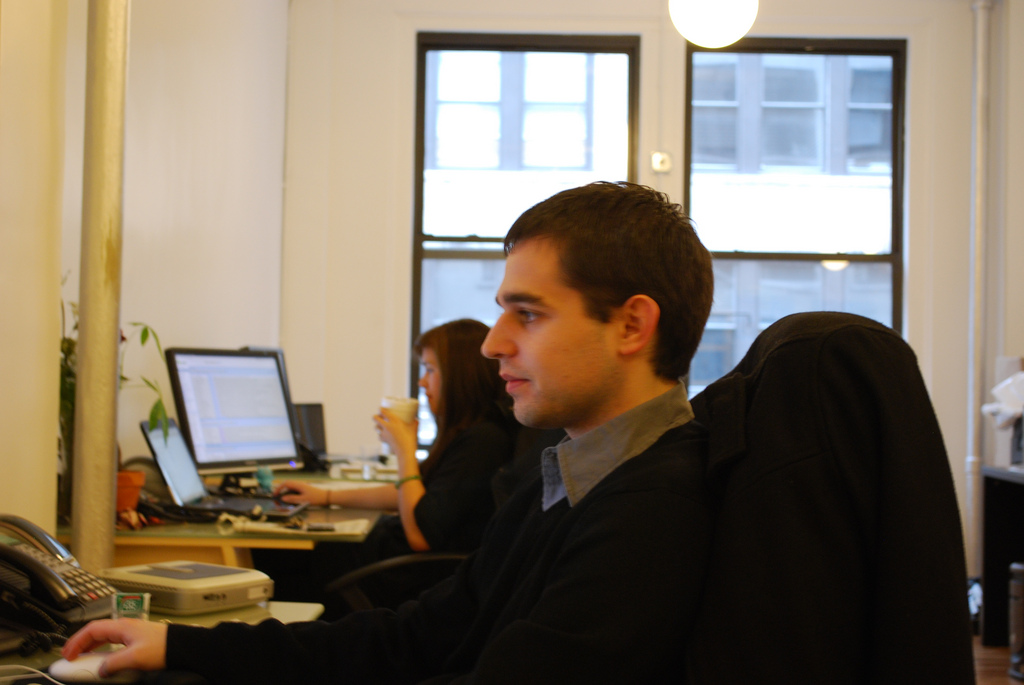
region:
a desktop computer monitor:
[168, 344, 306, 477]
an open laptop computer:
[136, 413, 305, 527]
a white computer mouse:
[52, 654, 103, 678]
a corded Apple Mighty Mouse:
[49, 651, 116, 678]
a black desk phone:
[4, 508, 122, 630]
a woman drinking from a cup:
[276, 316, 540, 550]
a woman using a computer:
[138, 318, 543, 550]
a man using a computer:
[49, 181, 752, 681]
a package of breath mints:
[111, 587, 150, 620]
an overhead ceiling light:
[667, 0, 760, 51]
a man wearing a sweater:
[405, 222, 799, 676]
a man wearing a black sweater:
[388, 186, 762, 662]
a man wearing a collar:
[449, 173, 808, 607]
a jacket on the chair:
[688, 263, 996, 671]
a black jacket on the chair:
[679, 303, 1022, 636]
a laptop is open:
[130, 414, 307, 573]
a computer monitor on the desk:
[179, 335, 322, 484]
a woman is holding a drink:
[378, 320, 522, 567]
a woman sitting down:
[364, 319, 514, 618]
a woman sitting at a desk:
[340, 326, 517, 527]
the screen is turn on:
[157, 333, 314, 485]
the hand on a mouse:
[28, 603, 207, 681]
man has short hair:
[436, 166, 751, 558]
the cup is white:
[372, 381, 427, 457]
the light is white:
[650, 0, 777, 67]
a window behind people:
[389, 17, 936, 467]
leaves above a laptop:
[68, 271, 217, 518]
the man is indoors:
[68, 186, 742, 674]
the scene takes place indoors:
[6, 0, 1022, 677]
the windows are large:
[398, 47, 911, 452]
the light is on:
[676, 0, 762, 46]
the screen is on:
[167, 347, 301, 471]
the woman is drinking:
[375, 392, 423, 441]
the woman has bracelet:
[373, 397, 424, 458]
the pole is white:
[70, 3, 128, 574]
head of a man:
[382, 143, 776, 472]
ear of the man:
[587, 263, 704, 391]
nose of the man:
[459, 289, 559, 375]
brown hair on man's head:
[482, 155, 733, 326]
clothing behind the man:
[697, 272, 945, 539]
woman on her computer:
[195, 285, 516, 548]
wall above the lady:
[132, 142, 268, 298]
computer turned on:
[113, 316, 303, 516]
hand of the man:
[62, 562, 183, 683]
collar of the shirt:
[448, 364, 724, 536]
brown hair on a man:
[499, 188, 716, 378]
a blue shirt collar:
[480, 377, 693, 520]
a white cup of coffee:
[382, 387, 422, 439]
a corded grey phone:
[5, 506, 127, 644]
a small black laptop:
[135, 409, 304, 543]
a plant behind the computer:
[107, 319, 190, 500]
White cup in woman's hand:
[375, 378, 418, 452]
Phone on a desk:
[2, 494, 136, 635]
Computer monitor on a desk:
[166, 331, 316, 472]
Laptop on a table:
[130, 409, 307, 550]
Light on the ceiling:
[661, 4, 760, 56]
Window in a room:
[403, 27, 642, 240]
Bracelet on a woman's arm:
[384, 456, 423, 499]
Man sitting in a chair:
[455, 184, 791, 669]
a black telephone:
[1, 511, 131, 632]